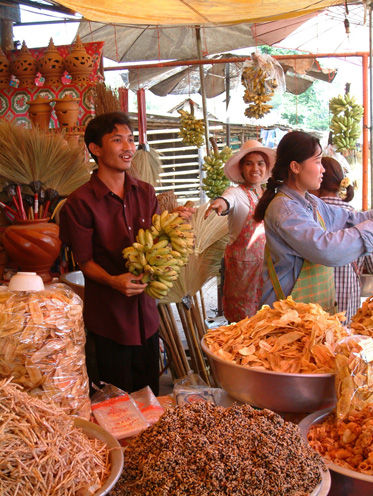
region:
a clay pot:
[57, 89, 83, 126]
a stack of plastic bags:
[99, 383, 161, 435]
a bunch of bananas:
[122, 202, 195, 297]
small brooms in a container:
[1, 130, 97, 224]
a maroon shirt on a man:
[73, 164, 187, 341]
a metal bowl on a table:
[198, 332, 363, 410]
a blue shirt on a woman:
[258, 183, 363, 316]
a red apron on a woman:
[213, 183, 277, 329]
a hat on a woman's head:
[202, 137, 276, 195]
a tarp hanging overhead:
[47, 1, 358, 27]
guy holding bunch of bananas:
[56, 99, 221, 292]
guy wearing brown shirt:
[55, 103, 183, 316]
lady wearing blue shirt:
[263, 137, 368, 322]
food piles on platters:
[12, 377, 306, 492]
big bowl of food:
[196, 298, 350, 401]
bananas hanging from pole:
[223, 45, 285, 133]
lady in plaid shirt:
[315, 166, 371, 315]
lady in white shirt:
[218, 134, 275, 212]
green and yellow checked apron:
[267, 176, 366, 327]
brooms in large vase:
[5, 114, 70, 272]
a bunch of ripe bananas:
[122, 212, 195, 295]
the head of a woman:
[274, 129, 324, 192]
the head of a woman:
[315, 154, 352, 199]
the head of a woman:
[238, 139, 267, 183]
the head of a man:
[82, 111, 136, 170]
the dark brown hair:
[82, 113, 129, 147]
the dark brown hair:
[250, 133, 322, 220]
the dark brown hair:
[319, 153, 356, 202]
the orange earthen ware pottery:
[28, 95, 52, 131]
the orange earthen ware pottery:
[53, 91, 83, 129]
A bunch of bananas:
[108, 191, 217, 306]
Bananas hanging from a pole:
[160, 51, 364, 164]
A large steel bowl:
[199, 292, 367, 419]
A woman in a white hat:
[211, 132, 294, 206]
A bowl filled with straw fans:
[3, 115, 97, 300]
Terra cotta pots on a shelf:
[22, 92, 88, 133]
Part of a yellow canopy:
[50, 0, 347, 44]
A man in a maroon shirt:
[58, 109, 191, 354]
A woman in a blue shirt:
[242, 128, 366, 325]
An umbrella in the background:
[124, 44, 335, 109]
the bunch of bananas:
[127, 211, 187, 289]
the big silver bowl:
[198, 335, 335, 409]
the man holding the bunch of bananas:
[64, 111, 193, 392]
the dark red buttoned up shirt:
[59, 169, 162, 340]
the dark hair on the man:
[86, 113, 127, 132]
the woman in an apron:
[213, 141, 274, 315]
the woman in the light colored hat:
[203, 137, 275, 320]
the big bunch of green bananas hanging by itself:
[325, 82, 366, 151]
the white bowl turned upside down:
[8, 270, 43, 290]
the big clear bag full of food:
[1, 285, 91, 417]